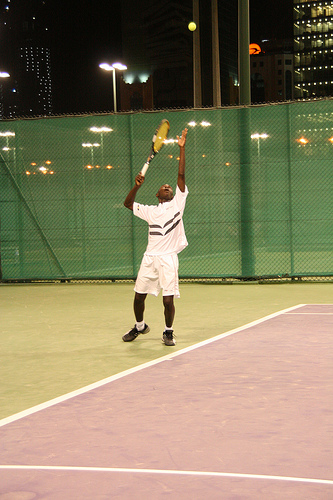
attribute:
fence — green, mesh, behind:
[0, 94, 331, 286]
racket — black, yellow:
[137, 118, 168, 176]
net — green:
[4, 107, 317, 278]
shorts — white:
[133, 251, 181, 296]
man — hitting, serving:
[120, 125, 197, 348]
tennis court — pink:
[61, 275, 330, 449]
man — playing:
[128, 150, 202, 383]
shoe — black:
[121, 322, 150, 343]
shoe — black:
[162, 328, 174, 347]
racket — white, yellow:
[138, 118, 170, 178]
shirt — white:
[131, 184, 189, 252]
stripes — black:
[148, 211, 179, 235]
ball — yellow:
[186, 20, 196, 30]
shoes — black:
[120, 316, 178, 345]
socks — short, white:
[132, 319, 147, 333]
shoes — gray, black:
[121, 322, 149, 341]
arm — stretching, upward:
[172, 126, 194, 194]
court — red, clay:
[1, 303, 326, 498]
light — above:
[92, 35, 144, 100]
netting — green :
[0, 90, 333, 292]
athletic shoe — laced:
[122, 320, 149, 341]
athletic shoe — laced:
[162, 325, 175, 345]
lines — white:
[1, 302, 331, 483]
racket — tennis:
[133, 119, 173, 169]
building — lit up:
[0, 0, 53, 118]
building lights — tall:
[290, 1, 332, 159]